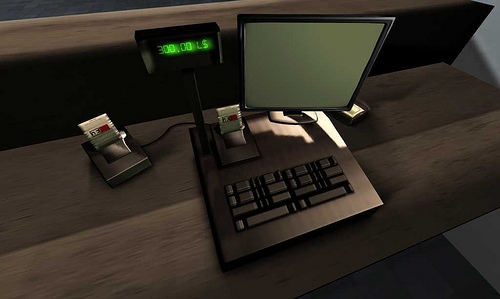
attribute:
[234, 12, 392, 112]
moniter — black, flat, grey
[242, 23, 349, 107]
screen — grey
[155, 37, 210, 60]
letters — glowing, green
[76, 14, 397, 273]
register — electronic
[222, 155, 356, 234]
buttons — black, different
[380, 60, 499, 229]
counter — brown, wooden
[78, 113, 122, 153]
paper — white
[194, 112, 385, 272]
base — shiney, metal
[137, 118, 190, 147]
cord — short, black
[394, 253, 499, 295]
floor — dark, grey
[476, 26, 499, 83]
wall — grey